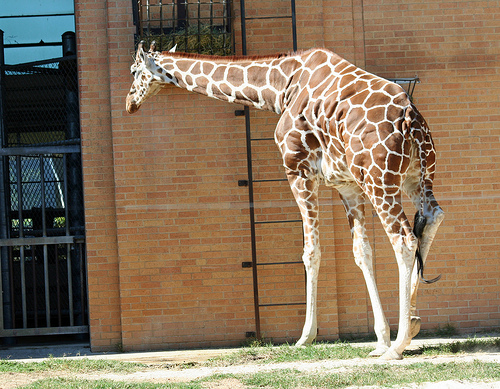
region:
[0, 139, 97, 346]
metal barrier on giraffe pen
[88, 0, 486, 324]
brick wall in giraffe pen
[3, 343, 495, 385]
sparse green grass in giraffe pen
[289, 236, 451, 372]
white legs of giraffe in pen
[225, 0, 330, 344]
black metal ladder on side of brick building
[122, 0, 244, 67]
metal cover over windows in wall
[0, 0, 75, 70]
blue sky in the background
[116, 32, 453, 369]
brown and white giraffe in a pen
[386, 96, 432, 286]
brown and white tail of giraffe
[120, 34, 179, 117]
head of giraffe with horns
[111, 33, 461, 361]
A giraffe in front of a building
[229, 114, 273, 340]
A black ladder attached to building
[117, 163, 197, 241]
Multiple shades of orange brick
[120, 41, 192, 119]
The head of a giraffe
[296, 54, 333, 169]
The spots of a giraffe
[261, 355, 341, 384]
Dry green grass and dirt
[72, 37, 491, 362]
A giraffe out in civilization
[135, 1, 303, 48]
Part of a fire escape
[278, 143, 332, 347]
The leg of a giraffe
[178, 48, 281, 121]
The neck of a giraffe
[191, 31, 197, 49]
Straw on a building window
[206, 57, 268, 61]
Hair bristles on the neck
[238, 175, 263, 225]
A ladder against a wall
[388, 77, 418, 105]
A brace on a giraffe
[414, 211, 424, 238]
Tail between the legs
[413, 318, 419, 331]
Hoof raised up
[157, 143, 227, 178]
A brick wall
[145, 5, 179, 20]
Bars on a window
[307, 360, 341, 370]
A bare patch on the ground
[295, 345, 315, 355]
Grass below a hoof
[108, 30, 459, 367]
a giraffe on side a building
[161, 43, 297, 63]
mane of giraffe along the neck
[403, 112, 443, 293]
tail of giraffe with turf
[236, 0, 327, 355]
a ladder behind a giraffe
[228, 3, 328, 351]
a black ladder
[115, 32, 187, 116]
horns on head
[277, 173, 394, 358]
front legs of giraffe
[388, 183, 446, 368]
back legs of giraffe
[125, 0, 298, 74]
window next to ladder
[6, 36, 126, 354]
a fence on side a building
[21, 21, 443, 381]
picture taken outdoors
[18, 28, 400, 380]
picture taken during the day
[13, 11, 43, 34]
the sky is void of clouds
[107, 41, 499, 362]
a solitary giraffe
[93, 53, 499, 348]
the giraffe is next to the building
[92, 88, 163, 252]
the building is made of bricks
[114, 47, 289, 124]
the giraffe's neck is partially down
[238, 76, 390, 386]
a metal ladder next to the wall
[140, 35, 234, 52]
a feeding troth on the wall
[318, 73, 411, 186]
the giraffe has brown spots